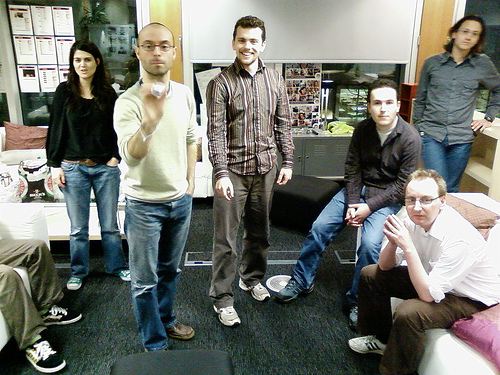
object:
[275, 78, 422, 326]
man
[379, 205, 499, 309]
shirt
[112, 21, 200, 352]
man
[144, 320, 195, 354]
shoes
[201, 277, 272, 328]
footwear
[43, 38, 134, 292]
woman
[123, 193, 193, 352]
jeans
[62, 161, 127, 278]
jeans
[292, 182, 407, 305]
jeans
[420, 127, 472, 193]
jeans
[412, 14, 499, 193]
man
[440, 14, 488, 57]
brown hair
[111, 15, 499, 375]
men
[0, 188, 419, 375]
green carpet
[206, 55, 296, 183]
shirt striped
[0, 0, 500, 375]
people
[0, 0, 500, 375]
office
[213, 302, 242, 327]
shoes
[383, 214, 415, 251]
hand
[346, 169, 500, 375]
man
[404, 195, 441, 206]
glasses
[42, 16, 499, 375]
people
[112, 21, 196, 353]
person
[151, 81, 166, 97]
controller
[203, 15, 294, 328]
man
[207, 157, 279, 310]
pants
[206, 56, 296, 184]
shirt